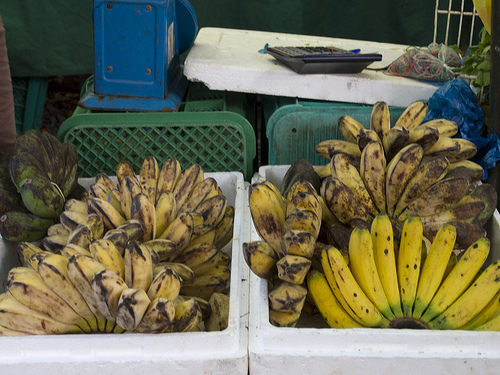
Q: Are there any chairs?
A: No, there are no chairs.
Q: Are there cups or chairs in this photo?
A: No, there are no chairs or cups.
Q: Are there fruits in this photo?
A: Yes, there is a fruit.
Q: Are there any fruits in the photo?
A: Yes, there is a fruit.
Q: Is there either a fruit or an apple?
A: Yes, there is a fruit.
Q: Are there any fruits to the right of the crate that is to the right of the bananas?
A: Yes, there is a fruit to the right of the crate.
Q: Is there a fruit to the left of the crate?
A: No, the fruit is to the right of the crate.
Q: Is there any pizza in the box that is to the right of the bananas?
A: No, there is a fruit in the box.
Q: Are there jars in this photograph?
A: No, there are no jars.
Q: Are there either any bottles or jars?
A: No, there are no jars or bottles.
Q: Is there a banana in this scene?
A: Yes, there are bananas.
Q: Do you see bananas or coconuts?
A: Yes, there are bananas.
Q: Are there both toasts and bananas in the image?
A: No, there are bananas but no toasts.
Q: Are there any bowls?
A: No, there are no bowls.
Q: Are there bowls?
A: No, there are no bowls.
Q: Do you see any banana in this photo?
A: Yes, there are bananas.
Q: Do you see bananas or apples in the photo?
A: Yes, there are bananas.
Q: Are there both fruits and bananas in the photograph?
A: Yes, there are both bananas and a fruit.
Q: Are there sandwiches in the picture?
A: No, there are no sandwiches.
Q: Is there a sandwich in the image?
A: No, there are no sandwiches.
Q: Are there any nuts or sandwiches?
A: No, there are no sandwiches or nuts.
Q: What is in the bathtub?
A: The bananas are in the bathtub.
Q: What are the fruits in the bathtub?
A: The fruits are bananas.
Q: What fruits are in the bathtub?
A: The fruits are bananas.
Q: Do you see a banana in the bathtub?
A: Yes, there are bananas in the bathtub.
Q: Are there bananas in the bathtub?
A: Yes, there are bananas in the bathtub.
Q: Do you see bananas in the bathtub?
A: Yes, there are bananas in the bathtub.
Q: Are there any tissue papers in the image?
A: No, there are no tissue papers.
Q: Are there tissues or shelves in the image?
A: No, there are no tissues or shelves.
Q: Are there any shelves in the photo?
A: No, there are no shelves.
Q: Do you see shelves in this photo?
A: No, there are no shelves.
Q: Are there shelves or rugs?
A: No, there are no shelves or rugs.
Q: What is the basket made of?
A: The basket is made of plastic.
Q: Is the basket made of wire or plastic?
A: The basket is made of plastic.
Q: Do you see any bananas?
A: Yes, there is a banana.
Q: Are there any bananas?
A: Yes, there is a banana.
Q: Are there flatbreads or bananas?
A: Yes, there is a banana.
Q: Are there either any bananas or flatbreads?
A: Yes, there is a banana.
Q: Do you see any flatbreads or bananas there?
A: Yes, there is a banana.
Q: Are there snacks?
A: No, there are no snacks.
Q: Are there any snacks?
A: No, there are no snacks.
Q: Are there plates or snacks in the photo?
A: No, there are no snacks or plates.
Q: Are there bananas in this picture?
A: Yes, there are bananas.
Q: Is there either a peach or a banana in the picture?
A: Yes, there are bananas.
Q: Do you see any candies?
A: No, there are no candies.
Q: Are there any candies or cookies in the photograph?
A: No, there are no candies or cookies.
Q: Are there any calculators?
A: Yes, there is a calculator.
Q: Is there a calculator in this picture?
A: Yes, there is a calculator.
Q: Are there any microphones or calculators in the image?
A: Yes, there is a calculator.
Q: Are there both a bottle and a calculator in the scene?
A: No, there is a calculator but no bottles.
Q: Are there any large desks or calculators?
A: Yes, there is a large calculator.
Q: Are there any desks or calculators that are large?
A: Yes, the calculator is large.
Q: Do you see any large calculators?
A: Yes, there is a large calculator.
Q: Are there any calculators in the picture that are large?
A: Yes, there is a calculator that is large.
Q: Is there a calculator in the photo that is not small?
A: Yes, there is a large calculator.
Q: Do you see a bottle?
A: No, there are no bottles.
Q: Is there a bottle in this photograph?
A: No, there are no bottles.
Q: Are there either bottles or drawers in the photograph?
A: No, there are no bottles or drawers.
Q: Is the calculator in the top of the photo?
A: Yes, the calculator is in the top of the image.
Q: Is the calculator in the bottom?
A: No, the calculator is in the top of the image.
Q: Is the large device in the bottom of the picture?
A: No, the calculator is in the top of the image.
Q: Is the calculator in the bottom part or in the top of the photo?
A: The calculator is in the top of the image.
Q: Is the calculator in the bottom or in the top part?
A: The calculator is in the top of the image.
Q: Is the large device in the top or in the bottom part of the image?
A: The calculator is in the top of the image.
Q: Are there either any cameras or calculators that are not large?
A: No, there is a calculator but it is large.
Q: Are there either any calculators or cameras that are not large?
A: No, there is a calculator but it is large.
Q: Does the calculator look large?
A: Yes, the calculator is large.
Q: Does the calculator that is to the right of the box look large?
A: Yes, the calculator is large.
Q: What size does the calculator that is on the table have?
A: The calculator has large size.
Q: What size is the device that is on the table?
A: The calculator is large.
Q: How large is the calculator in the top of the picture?
A: The calculator is large.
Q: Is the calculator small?
A: No, the calculator is large.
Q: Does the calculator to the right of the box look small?
A: No, the calculator is large.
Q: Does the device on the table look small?
A: No, the calculator is large.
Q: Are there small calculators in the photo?
A: No, there is a calculator but it is large.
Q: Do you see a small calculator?
A: No, there is a calculator but it is large.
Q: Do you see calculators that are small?
A: No, there is a calculator but it is large.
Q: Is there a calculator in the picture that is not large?
A: No, there is a calculator but it is large.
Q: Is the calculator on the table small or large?
A: The calculator is large.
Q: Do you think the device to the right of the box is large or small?
A: The calculator is large.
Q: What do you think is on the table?
A: The calculator is on the table.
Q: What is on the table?
A: The calculator is on the table.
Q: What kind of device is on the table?
A: The device is a calculator.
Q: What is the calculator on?
A: The calculator is on the table.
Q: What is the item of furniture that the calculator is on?
A: The piece of furniture is a table.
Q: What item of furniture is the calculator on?
A: The calculator is on the table.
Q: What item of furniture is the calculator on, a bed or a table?
A: The calculator is on a table.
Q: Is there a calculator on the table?
A: Yes, there is a calculator on the table.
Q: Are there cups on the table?
A: No, there is a calculator on the table.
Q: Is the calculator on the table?
A: Yes, the calculator is on the table.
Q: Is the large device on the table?
A: Yes, the calculator is on the table.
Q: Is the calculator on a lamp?
A: No, the calculator is on the table.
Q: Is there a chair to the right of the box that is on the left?
A: No, there is a calculator to the right of the box.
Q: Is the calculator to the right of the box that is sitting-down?
A: Yes, the calculator is to the right of the box.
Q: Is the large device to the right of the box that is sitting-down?
A: Yes, the calculator is to the right of the box.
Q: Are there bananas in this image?
A: Yes, there are bananas.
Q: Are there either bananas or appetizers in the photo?
A: Yes, there are bananas.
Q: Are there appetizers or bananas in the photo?
A: Yes, there are bananas.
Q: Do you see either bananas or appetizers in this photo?
A: Yes, there are bananas.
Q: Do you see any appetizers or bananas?
A: Yes, there are bananas.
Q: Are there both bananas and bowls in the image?
A: No, there are bananas but no bowls.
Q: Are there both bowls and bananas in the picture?
A: No, there are bananas but no bowls.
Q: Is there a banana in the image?
A: Yes, there are bananas.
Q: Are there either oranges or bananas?
A: Yes, there are bananas.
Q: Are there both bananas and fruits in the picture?
A: Yes, there are both bananas and a fruit.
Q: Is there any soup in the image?
A: No, there is no soup.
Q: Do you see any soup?
A: No, there is no soup.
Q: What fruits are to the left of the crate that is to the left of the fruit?
A: The fruits are bananas.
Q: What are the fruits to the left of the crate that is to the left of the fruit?
A: The fruits are bananas.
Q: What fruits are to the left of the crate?
A: The fruits are bananas.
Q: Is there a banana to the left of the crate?
A: Yes, there are bananas to the left of the crate.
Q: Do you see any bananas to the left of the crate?
A: Yes, there are bananas to the left of the crate.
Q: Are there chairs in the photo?
A: No, there are no chairs.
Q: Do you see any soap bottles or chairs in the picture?
A: No, there are no chairs or soap bottles.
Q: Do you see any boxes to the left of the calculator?
A: Yes, there is a box to the left of the calculator.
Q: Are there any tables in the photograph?
A: Yes, there is a table.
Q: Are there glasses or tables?
A: Yes, there is a table.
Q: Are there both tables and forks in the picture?
A: No, there is a table but no forks.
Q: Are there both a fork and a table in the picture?
A: No, there is a table but no forks.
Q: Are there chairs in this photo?
A: No, there are no chairs.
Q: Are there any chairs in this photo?
A: No, there are no chairs.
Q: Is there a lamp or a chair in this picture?
A: No, there are no chairs or lamps.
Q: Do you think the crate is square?
A: Yes, the crate is square.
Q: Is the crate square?
A: Yes, the crate is square.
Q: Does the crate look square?
A: Yes, the crate is square.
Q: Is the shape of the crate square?
A: Yes, the crate is square.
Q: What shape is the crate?
A: The crate is square.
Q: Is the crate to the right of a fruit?
A: No, the crate is to the left of a fruit.